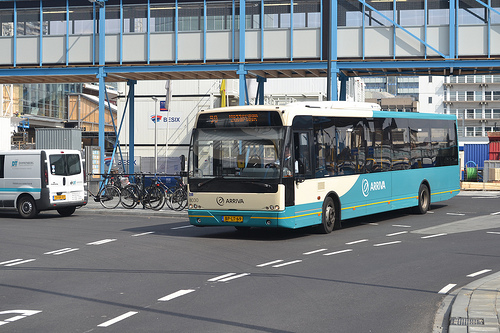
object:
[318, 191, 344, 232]
wheel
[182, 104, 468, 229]
bus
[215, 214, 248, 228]
license plate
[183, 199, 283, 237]
headlights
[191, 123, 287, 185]
windshield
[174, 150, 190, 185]
mirror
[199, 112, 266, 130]
digital display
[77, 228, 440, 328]
stripes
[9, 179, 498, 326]
road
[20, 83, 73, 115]
window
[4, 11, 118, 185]
building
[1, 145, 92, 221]
truck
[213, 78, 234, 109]
pole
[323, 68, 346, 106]
pole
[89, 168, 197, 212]
bikes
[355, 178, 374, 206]
logo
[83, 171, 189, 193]
rack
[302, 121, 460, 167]
window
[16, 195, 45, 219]
wheel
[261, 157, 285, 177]
steering wheel